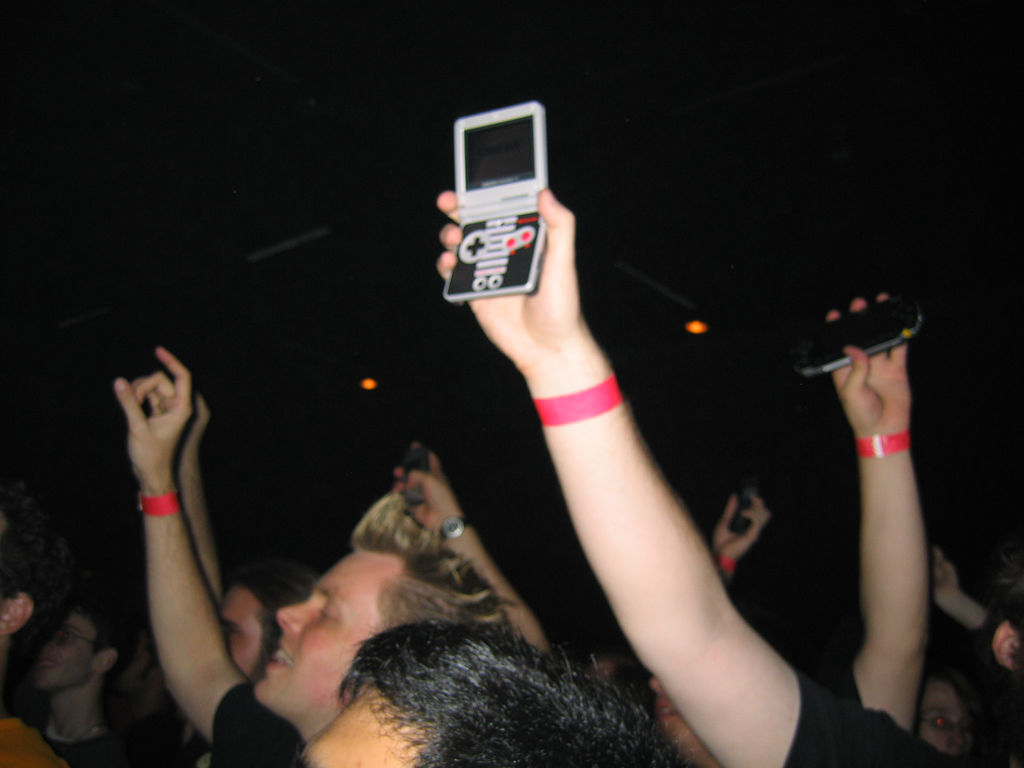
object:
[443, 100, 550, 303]
nintendo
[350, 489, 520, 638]
hair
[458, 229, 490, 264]
pad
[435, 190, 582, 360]
hand